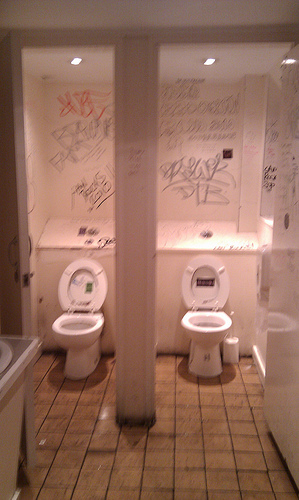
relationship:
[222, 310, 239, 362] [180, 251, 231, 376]
bowl cleaner to right toilet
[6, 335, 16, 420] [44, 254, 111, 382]
sink to left toilet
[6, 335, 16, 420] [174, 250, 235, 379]
sink to left toilet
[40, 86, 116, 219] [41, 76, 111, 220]
graffiti covers wall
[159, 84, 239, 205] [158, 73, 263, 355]
graffiti covers wall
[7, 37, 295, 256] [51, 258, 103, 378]
graffiti above toilet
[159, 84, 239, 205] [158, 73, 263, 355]
graffiti written on wall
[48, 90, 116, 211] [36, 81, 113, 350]
graffiti written on wall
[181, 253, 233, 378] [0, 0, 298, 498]
toilet in bathroom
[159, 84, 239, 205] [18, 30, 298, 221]
graffiti on wall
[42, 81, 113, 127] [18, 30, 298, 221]
orange writing on wall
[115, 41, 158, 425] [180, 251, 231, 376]
column near toilet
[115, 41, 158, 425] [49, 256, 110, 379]
column near toilet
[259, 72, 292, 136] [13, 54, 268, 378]
mirror to right of toilet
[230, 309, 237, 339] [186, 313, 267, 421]
toilet brush put away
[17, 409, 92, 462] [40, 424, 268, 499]
part of a floor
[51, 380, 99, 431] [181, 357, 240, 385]
part of a shadow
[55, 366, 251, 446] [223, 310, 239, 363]
part of a bowl cleaner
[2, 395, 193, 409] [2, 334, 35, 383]
part of a sink